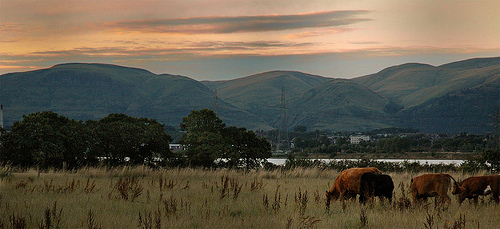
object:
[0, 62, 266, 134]
mountains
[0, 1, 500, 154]
background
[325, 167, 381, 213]
animals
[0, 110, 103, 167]
trees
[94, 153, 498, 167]
water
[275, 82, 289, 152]
tower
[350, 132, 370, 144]
buildings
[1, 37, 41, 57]
sun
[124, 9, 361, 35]
clouds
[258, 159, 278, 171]
bushes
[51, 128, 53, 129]
leaves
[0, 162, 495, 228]
field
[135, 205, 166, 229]
weeds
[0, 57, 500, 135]
range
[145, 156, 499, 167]
lake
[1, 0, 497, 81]
sky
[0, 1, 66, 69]
sunset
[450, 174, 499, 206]
cow